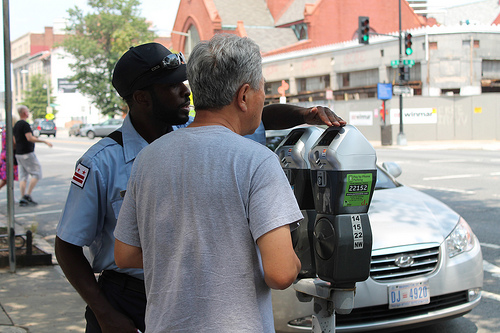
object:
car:
[270, 128, 484, 333]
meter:
[274, 117, 383, 290]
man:
[105, 34, 302, 332]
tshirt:
[108, 124, 310, 332]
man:
[13, 107, 52, 209]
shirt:
[13, 119, 36, 154]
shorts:
[16, 153, 43, 183]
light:
[361, 35, 370, 42]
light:
[405, 47, 416, 56]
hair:
[186, 32, 263, 115]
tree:
[19, 78, 55, 124]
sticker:
[342, 170, 373, 208]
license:
[386, 280, 430, 310]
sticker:
[349, 214, 366, 250]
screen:
[317, 130, 339, 146]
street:
[0, 136, 500, 332]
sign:
[390, 58, 413, 69]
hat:
[112, 38, 191, 90]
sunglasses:
[119, 49, 187, 94]